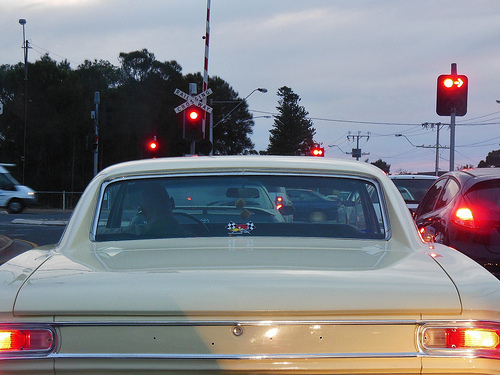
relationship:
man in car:
[97, 182, 197, 236] [0, 150, 499, 373]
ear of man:
[168, 194, 176, 209] [96, 183, 191, 237]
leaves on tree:
[3, 48, 318, 177] [256, 78, 328, 159]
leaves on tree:
[282, 99, 306, 119] [254, 83, 320, 154]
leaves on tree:
[0, 48, 317, 177] [105, 59, 159, 161]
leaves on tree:
[0, 49, 253, 205] [2, 57, 102, 191]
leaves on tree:
[0, 49, 253, 205] [94, 48, 183, 166]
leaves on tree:
[0, 49, 253, 205] [176, 74, 253, 151]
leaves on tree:
[0, 49, 253, 205] [263, 86, 315, 153]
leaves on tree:
[0, 48, 317, 177] [269, 73, 317, 160]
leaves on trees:
[0, 47, 259, 193] [2, 45, 316, 223]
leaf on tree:
[273, 107, 283, 112] [263, 87, 325, 157]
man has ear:
[127, 180, 194, 236] [136, 206, 148, 221]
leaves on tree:
[267, 84, 324, 155] [257, 81, 326, 151]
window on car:
[92, 162, 408, 251] [54, 165, 489, 368]